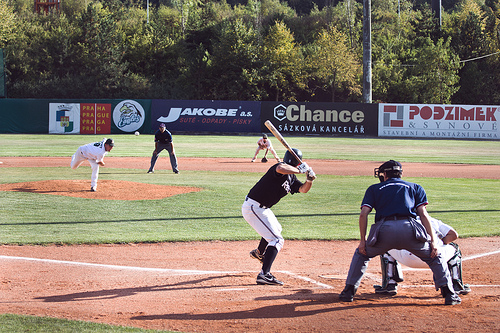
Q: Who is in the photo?
A: People.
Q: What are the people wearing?
A: Clothes.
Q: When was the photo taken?
A: Daytime.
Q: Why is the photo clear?
A: During daytime.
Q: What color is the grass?
A: Green.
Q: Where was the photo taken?
A: Baseball field.